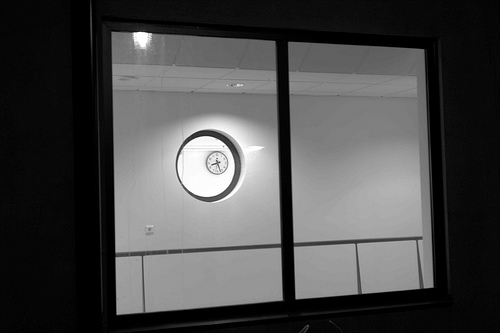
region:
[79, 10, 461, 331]
The double window is open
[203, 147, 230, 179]
The clock on the wall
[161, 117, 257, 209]
The window on the wall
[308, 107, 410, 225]
The color of the wall is white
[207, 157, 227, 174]
The hands on the clock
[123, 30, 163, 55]
The light on the top of the ceiling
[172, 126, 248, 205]
The window is a circular shape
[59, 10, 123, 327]
The side of the window seal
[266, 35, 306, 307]
The middle of the window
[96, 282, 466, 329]
The bottom of the window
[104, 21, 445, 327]
glass window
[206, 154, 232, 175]
a clock seen through a circle window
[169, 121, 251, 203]
a circle shape window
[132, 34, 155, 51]
light glaring on the ceiling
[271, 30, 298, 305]
black window pane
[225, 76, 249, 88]
light fixture on the ceiling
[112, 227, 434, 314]
black railing in a building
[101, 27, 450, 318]
glass window view of inside a building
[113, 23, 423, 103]
ceiling in a building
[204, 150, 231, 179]
clock on the wall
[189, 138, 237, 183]
clock shown through the windows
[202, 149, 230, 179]
time on the clock is 8:27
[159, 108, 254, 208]
porthole window in the wall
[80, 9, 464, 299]
double pane window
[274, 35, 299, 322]
metal part of the frame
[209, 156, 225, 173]
black clock hands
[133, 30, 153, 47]
light shining at the top of the window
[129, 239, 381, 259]
rail outside of the window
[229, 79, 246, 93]
recessed light fixture in the ceiling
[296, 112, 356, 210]
wall outside the window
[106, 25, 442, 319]
a very large window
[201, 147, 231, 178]
a clock on the wall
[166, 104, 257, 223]
a very large hole in the wall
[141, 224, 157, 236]
a small light switch on the wall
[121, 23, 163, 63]
a very bright light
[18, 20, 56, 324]
the outside wall on a building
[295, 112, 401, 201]
a wall on the inside of the building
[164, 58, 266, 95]
the ceiling of the building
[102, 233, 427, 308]
some rails in the inside of the building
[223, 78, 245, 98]
a small light fixture with no bulb